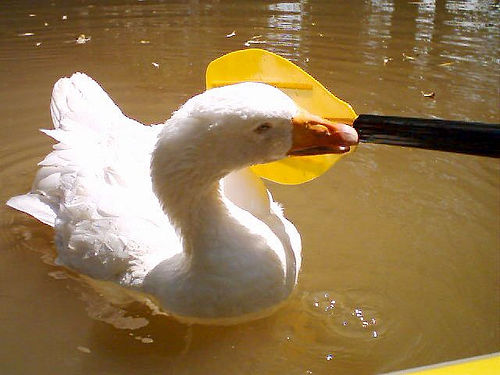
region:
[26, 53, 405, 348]
Duck in the water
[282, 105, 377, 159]
The duck has an orange bill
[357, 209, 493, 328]
The water is a murky color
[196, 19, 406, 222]
Paddle with a yellow head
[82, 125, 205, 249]
The duck has white feathers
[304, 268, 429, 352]
Ripple in the water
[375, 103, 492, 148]
The paddle has a black pole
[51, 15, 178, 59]
Leaves floating in the water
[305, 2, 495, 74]
Light reflecting off the water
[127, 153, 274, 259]
The duck has a long neck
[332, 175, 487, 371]
a body of water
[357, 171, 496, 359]
a body of murky water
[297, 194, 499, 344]
a body of water that is murky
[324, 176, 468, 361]
a body of water that is calm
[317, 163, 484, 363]
a body of calm water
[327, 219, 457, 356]
a body of calm murky water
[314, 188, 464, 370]
a body of calm water that is murky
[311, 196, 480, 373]
a body of murky water that is calm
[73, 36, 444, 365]
a duck in the water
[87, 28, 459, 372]
a duck swimming in the water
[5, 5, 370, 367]
this is a duck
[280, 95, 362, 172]
beak of the duck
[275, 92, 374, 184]
beak of the duck is orange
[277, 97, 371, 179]
beak of the duck is open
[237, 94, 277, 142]
eye on the duck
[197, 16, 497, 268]
this is a boat paddle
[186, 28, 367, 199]
boat paddle is yellow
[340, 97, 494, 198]
stick of paddle is black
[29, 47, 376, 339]
the duck is white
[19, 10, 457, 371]
duck is in the water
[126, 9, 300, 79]
a body of water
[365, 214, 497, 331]
a body of water that is calm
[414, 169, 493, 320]
a body of calm water that is murky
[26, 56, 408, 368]
a duck in the murky water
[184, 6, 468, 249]
a black and yellow paddle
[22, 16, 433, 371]
a white duck swimming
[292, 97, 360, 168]
The swan's bill is orange.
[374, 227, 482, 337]
The water is brown.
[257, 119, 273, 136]
The swan's eye is small.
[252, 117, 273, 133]
The swan's eye is round.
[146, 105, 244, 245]
The swan's neck is long.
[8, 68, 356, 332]
The swan's feathers are white.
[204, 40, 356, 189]
The paddle is yellow.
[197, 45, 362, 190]
The paddle is made of plastic.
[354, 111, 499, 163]
The paddle pole is black.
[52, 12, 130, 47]
The leaves are in the water.